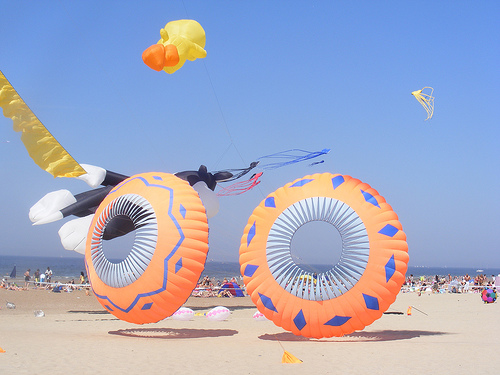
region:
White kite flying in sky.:
[408, 74, 438, 126]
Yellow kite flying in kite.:
[143, 28, 195, 73]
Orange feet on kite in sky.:
[146, 41, 189, 79]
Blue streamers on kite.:
[267, 145, 334, 172]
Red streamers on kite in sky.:
[218, 176, 261, 196]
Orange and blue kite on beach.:
[246, 198, 413, 333]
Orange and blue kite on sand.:
[82, 195, 177, 289]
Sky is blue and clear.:
[271, 58, 324, 100]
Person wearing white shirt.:
[41, 267, 56, 280]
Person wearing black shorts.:
[19, 270, 34, 286]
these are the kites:
[64, 175, 402, 322]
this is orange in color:
[248, 164, 405, 327]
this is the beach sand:
[204, 335, 254, 373]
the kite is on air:
[120, 20, 215, 76]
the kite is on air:
[141, 12, 219, 65]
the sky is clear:
[271, 6, 364, 101]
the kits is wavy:
[269, 140, 339, 165]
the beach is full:
[426, 264, 488, 299]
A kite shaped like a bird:
[141, 18, 211, 75]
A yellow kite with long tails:
[409, 85, 440, 120]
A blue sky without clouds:
[3, 3, 493, 264]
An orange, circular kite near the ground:
[238, 174, 408, 336]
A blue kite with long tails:
[262, 145, 332, 171]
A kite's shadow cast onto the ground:
[106, 325, 240, 341]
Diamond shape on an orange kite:
[361, 291, 381, 311]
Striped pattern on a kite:
[296, 201, 329, 218]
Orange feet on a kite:
[141, 43, 179, 71]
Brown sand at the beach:
[13, 291, 498, 373]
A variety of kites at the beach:
[12, 6, 457, 342]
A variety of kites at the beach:
[10, 10, 441, 340]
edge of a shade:
[286, 327, 313, 349]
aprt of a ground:
[214, 301, 230, 327]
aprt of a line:
[278, 288, 293, 310]